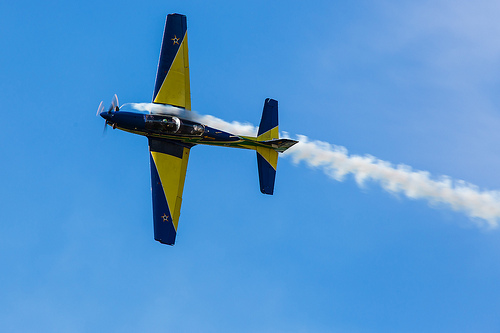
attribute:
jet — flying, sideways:
[96, 10, 300, 247]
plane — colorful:
[94, 10, 297, 247]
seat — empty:
[182, 120, 202, 137]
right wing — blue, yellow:
[150, 10, 192, 108]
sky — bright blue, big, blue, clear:
[1, 1, 484, 331]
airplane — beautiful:
[96, 11, 299, 247]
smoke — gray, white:
[119, 100, 484, 235]